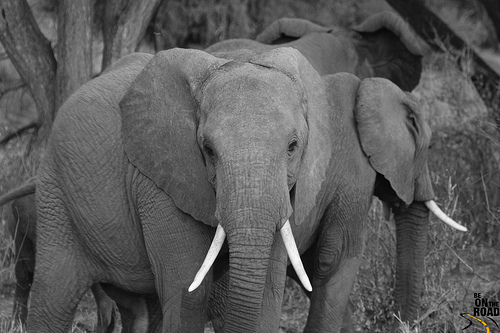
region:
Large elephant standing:
[30, 45, 340, 326]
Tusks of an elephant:
[172, 208, 319, 300]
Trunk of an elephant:
[216, 196, 271, 323]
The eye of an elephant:
[274, 132, 309, 162]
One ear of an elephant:
[115, 48, 231, 232]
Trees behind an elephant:
[0, 33, 110, 128]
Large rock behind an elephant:
[395, 48, 497, 217]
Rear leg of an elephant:
[19, 153, 96, 332]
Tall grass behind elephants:
[439, 148, 486, 244]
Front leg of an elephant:
[310, 241, 348, 330]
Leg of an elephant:
[309, 210, 351, 330]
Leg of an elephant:
[146, 212, 208, 327]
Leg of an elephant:
[261, 219, 288, 331]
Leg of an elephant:
[23, 187, 85, 329]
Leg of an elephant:
[94, 288, 115, 322]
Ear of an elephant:
[115, 40, 228, 213]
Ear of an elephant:
[254, 33, 339, 235]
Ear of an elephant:
[353, 77, 423, 221]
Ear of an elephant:
[353, 11, 448, 103]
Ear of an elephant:
[241, 8, 356, 74]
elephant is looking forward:
[62, 72, 351, 329]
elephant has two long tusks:
[195, 198, 317, 301]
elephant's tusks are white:
[169, 204, 380, 321]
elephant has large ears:
[96, 43, 306, 248]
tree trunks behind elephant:
[10, 15, 134, 90]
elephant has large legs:
[15, 129, 222, 329]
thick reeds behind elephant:
[373, 197, 495, 329]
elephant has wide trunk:
[225, 183, 290, 329]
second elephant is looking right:
[312, 49, 494, 322]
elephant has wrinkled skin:
[37, 106, 170, 263]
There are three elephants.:
[16, 3, 471, 329]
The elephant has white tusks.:
[185, 223, 312, 296]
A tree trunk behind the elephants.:
[0, 0, 156, 146]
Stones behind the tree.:
[0, 35, 90, 256]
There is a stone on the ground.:
[395, 48, 487, 130]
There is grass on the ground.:
[285, 113, 498, 330]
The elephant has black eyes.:
[196, 135, 301, 156]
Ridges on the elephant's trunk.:
[226, 193, 271, 329]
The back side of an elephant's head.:
[255, 7, 425, 82]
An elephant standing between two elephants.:
[313, 73, 470, 332]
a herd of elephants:
[52, 20, 462, 330]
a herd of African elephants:
[24, 8, 480, 328]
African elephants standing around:
[24, 13, 468, 332]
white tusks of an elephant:
[183, 213, 335, 298]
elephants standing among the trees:
[1, 5, 453, 327]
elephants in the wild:
[37, 31, 453, 331]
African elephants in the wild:
[26, 0, 481, 332]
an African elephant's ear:
[105, 43, 217, 223]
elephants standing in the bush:
[11, 5, 489, 330]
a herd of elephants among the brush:
[16, 15, 471, 332]